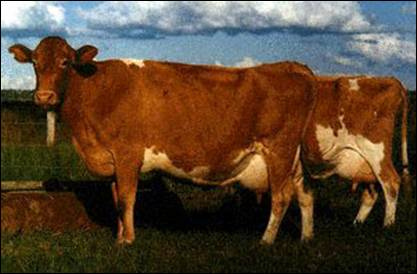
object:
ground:
[0, 196, 417, 273]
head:
[5, 35, 99, 108]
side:
[113, 62, 294, 166]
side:
[320, 78, 393, 158]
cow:
[9, 35, 313, 246]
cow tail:
[397, 92, 414, 189]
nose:
[34, 88, 56, 105]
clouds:
[0, 0, 68, 38]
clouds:
[326, 32, 415, 74]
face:
[31, 35, 72, 107]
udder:
[334, 147, 376, 183]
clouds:
[75, 0, 372, 36]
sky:
[0, 0, 416, 92]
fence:
[0, 92, 95, 181]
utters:
[335, 149, 380, 192]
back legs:
[257, 150, 298, 244]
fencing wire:
[0, 120, 62, 127]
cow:
[222, 75, 411, 226]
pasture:
[0, 88, 417, 273]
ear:
[72, 44, 99, 65]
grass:
[0, 200, 416, 274]